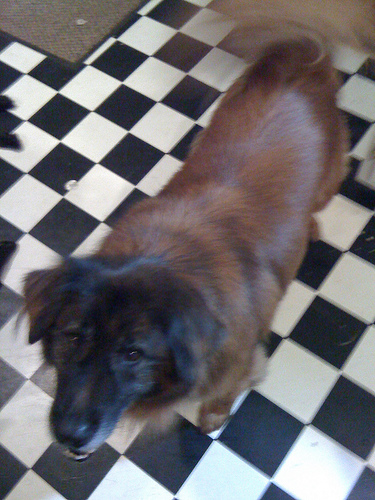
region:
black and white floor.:
[4, 1, 372, 497]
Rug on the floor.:
[1, 3, 151, 71]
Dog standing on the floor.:
[30, 1, 371, 458]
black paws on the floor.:
[0, 82, 27, 278]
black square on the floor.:
[286, 292, 365, 369]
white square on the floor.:
[63, 108, 130, 165]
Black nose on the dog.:
[48, 400, 106, 453]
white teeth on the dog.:
[53, 440, 101, 463]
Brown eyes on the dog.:
[58, 322, 150, 367]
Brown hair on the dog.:
[23, 0, 372, 467]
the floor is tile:
[35, 89, 118, 188]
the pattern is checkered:
[57, 114, 143, 173]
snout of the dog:
[50, 404, 123, 461]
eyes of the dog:
[39, 320, 140, 366]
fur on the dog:
[190, 195, 288, 219]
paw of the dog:
[198, 405, 225, 433]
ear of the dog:
[177, 300, 222, 380]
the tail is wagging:
[270, 10, 339, 82]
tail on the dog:
[248, 5, 346, 67]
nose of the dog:
[15, 395, 89, 445]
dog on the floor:
[5, 35, 306, 483]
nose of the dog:
[65, 411, 93, 450]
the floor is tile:
[315, 451, 372, 498]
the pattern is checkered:
[251, 381, 275, 486]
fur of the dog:
[202, 170, 244, 278]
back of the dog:
[313, 62, 335, 72]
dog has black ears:
[31, 265, 224, 389]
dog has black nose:
[57, 400, 106, 440]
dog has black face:
[64, 270, 157, 421]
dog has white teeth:
[60, 444, 88, 465]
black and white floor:
[257, 373, 357, 493]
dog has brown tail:
[235, 1, 332, 88]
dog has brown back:
[134, 59, 290, 303]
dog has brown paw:
[183, 394, 231, 436]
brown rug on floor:
[1, 4, 137, 83]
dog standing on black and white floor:
[44, 129, 365, 417]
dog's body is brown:
[63, 49, 334, 436]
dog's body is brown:
[154, 80, 311, 413]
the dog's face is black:
[20, 238, 160, 449]